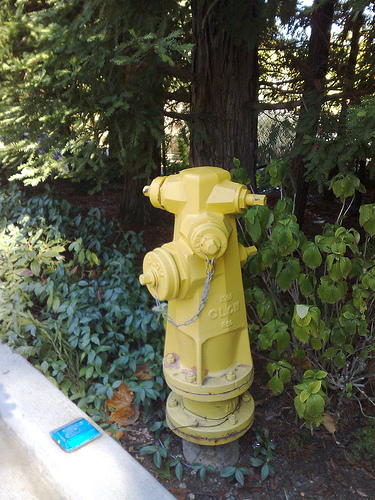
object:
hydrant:
[138, 165, 268, 446]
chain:
[154, 254, 218, 329]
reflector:
[48, 415, 102, 453]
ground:
[1, 192, 372, 499]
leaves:
[4, 202, 120, 337]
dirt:
[248, 449, 372, 500]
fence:
[160, 103, 301, 178]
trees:
[189, 1, 261, 194]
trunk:
[199, 5, 243, 150]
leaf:
[292, 302, 312, 322]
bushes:
[261, 215, 373, 420]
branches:
[251, 85, 373, 110]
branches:
[118, 105, 194, 122]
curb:
[0, 340, 179, 499]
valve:
[203, 239, 219, 255]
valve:
[244, 193, 268, 205]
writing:
[207, 291, 241, 330]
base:
[181, 437, 240, 472]